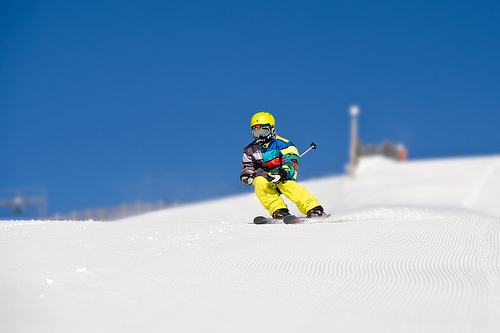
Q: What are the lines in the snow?
A: Scrapes.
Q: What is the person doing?
A: Skiing.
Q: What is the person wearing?
A: Ski suit.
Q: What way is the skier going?
A: Downhill.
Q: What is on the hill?
A: Snow.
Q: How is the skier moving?
A: On skis.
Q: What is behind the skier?
A: Pole.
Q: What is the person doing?
A: Skiing.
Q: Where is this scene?
A: Ski slope.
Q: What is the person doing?
A: Skiing.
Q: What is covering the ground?
A: Snow.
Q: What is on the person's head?
A: Helmet.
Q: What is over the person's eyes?
A: Goggles.